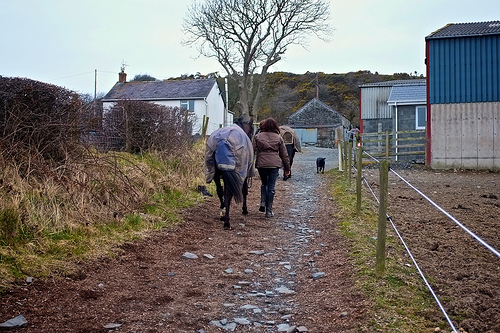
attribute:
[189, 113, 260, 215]
horse — brown 